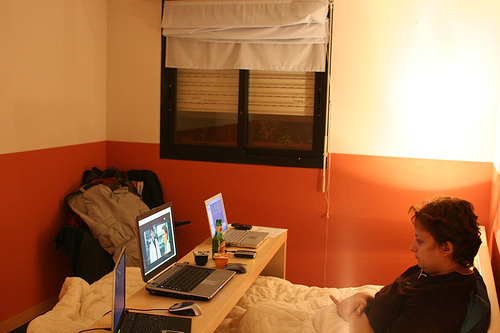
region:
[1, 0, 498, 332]
Laying in bed in a tiny room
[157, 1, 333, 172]
Blind is partway up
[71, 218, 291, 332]
Table going accross the bed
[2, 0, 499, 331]
Half the walls are red the other half white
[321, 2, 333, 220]
Cord hanging from the blinds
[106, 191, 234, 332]
Three screens turned on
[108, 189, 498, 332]
She is watching three different things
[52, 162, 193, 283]
Clothes in a pile in the corner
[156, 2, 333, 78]
Curtain hanging half way down the window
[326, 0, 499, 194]
Bright light in the corner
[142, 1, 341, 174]
black framed window on wall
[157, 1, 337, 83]
white shade on wall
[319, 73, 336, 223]
white cords attached to curtains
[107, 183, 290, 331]
three open laptops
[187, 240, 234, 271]
two cups of food on narrow white table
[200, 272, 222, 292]
square track pad on computer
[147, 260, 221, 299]
black keyboard on computer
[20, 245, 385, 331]
white bedspread on bed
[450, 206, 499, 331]
white bed headboard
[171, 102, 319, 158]
reflection in window glass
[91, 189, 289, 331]
three open laptops on table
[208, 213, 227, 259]
green bottle on table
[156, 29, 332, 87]
white curtain on front of window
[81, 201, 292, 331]
narrow white table across bed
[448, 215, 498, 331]
white headboard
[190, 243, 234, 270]
cups of food on table top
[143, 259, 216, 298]
black keyboard on laptop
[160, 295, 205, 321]
computer mouse on table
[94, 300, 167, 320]
black computer mouse wire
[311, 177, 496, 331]
Person is looking at the computers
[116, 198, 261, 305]
The middle laptop is black and silver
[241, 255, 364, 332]
The bed is white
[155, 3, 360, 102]
These are white curtains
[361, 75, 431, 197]
The paint is white and orange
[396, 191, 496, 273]
The hair is brown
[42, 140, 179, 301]
A bag in the corner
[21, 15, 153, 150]
This is the corner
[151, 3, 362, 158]
Window is half colored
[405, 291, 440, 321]
woman wearing black shirt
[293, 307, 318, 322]
white blanket on woman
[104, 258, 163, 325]
laptop one on table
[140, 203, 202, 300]
laptop two on table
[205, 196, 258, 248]
laptop three on table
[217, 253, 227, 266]
cup of orange jello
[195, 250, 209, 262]
cup of blue jello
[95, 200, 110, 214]
beige pants in laundry